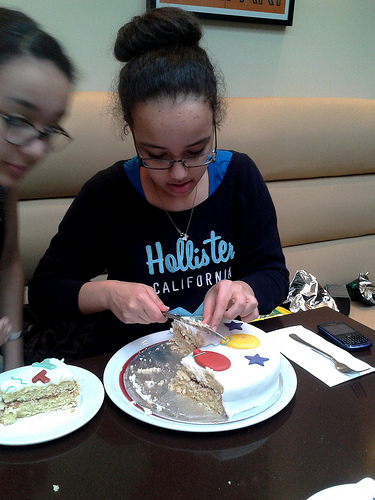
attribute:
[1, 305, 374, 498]
table — dark wooden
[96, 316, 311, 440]
plate — circular